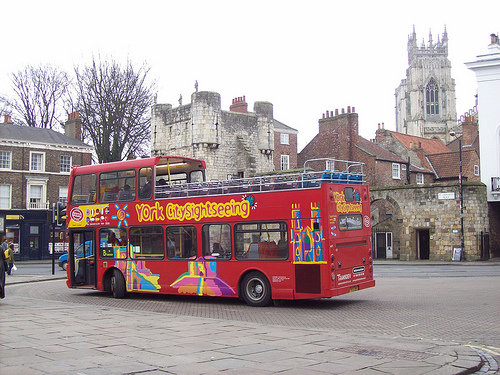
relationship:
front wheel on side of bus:
[109, 268, 126, 298] [48, 140, 406, 325]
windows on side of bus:
[68, 168, 155, 211] [57, 152, 384, 317]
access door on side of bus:
[69, 227, 98, 291] [39, 126, 384, 318]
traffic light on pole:
[45, 199, 63, 279] [41, 222, 62, 276]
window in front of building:
[379, 162, 408, 192] [272, 97, 495, 289]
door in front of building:
[405, 222, 439, 269] [152, 26, 500, 266]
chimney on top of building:
[225, 88, 255, 120] [145, 75, 312, 215]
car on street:
[52, 246, 81, 271] [18, 235, 136, 329]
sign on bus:
[74, 191, 255, 221] [48, 140, 406, 325]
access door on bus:
[63, 217, 99, 307] [57, 152, 384, 317]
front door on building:
[1, 206, 59, 263] [3, 109, 102, 260]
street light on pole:
[449, 132, 457, 137] [449, 139, 477, 261]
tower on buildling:
[390, 24, 459, 69] [388, 24, 462, 141]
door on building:
[409, 220, 438, 266] [374, 178, 498, 262]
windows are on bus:
[96, 215, 293, 266] [57, 152, 384, 317]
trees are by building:
[2, 58, 154, 184] [3, 109, 102, 260]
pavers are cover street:
[2, 259, 498, 339] [0, 230, 499, 370]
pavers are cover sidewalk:
[2, 259, 498, 339] [5, 294, 496, 374]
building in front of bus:
[0, 99, 94, 259] [57, 152, 384, 317]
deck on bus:
[141, 153, 366, 203] [58, 156, 379, 306]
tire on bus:
[104, 270, 129, 295] [57, 152, 384, 317]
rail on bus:
[159, 156, 374, 198] [58, 156, 379, 306]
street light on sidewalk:
[436, 127, 470, 262] [0, 236, 493, 369]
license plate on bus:
[341, 276, 371, 298] [57, 152, 384, 317]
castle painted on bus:
[278, 196, 332, 265] [57, 152, 384, 317]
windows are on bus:
[69, 161, 158, 201] [57, 152, 384, 317]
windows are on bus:
[93, 221, 290, 268] [57, 152, 384, 317]